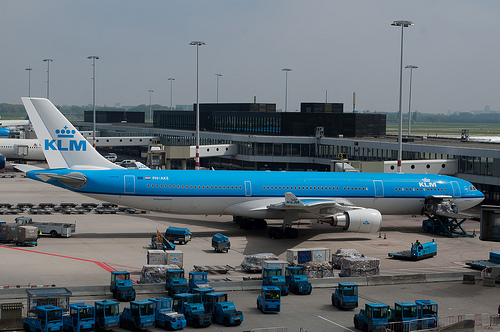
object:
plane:
[8, 95, 485, 240]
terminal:
[18, 95, 61, 115]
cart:
[387, 237, 438, 263]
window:
[389, 166, 396, 171]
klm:
[44, 138, 88, 153]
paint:
[0, 244, 138, 286]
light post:
[26, 66, 32, 96]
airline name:
[416, 180, 438, 187]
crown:
[54, 124, 77, 138]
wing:
[31, 172, 90, 189]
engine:
[328, 207, 385, 236]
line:
[0, 243, 95, 262]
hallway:
[88, 135, 160, 147]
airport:
[1, 158, 499, 331]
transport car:
[256, 284, 283, 313]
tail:
[19, 96, 129, 173]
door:
[371, 178, 384, 199]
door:
[122, 173, 137, 195]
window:
[146, 183, 150, 189]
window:
[262, 185, 266, 190]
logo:
[417, 177, 432, 184]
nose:
[466, 189, 485, 202]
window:
[394, 187, 399, 191]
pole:
[398, 25, 406, 174]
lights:
[391, 18, 414, 29]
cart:
[164, 225, 193, 246]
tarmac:
[1, 159, 500, 331]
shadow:
[303, 237, 373, 243]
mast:
[195, 44, 202, 170]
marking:
[315, 314, 356, 332]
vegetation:
[386, 121, 499, 138]